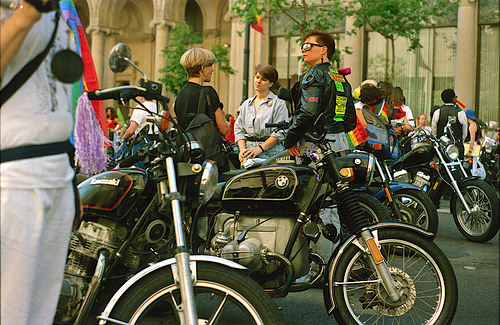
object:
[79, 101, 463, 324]
motorcycle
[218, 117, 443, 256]
motorcycle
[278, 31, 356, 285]
rider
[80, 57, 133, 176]
flag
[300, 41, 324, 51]
sunglasses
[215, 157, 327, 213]
gas tank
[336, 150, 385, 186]
headlight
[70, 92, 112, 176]
streamers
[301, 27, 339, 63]
head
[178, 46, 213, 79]
head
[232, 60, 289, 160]
woman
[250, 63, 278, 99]
head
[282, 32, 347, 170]
woman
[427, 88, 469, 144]
person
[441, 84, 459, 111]
head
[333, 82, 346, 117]
patches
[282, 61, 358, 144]
jacket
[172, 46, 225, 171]
woman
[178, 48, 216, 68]
blonde hair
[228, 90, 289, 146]
shirt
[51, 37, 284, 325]
motorcycles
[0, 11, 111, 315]
woman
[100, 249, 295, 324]
tire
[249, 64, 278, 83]
brown hair